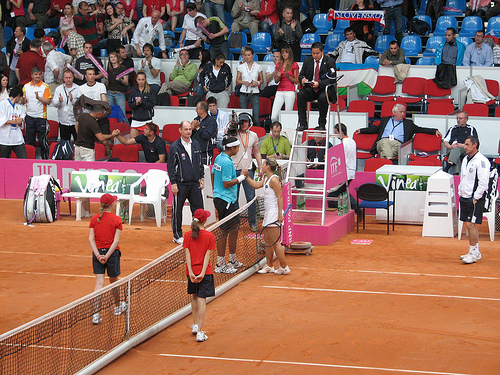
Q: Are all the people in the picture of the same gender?
A: No, they are both male and female.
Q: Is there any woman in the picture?
A: Yes, there are women.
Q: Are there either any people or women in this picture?
A: Yes, there are women.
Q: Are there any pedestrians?
A: No, there are no pedestrians.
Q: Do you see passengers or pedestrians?
A: No, there are no pedestrians or passengers.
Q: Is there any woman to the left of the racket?
A: Yes, there are women to the left of the racket.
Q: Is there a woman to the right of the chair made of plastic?
A: Yes, there are women to the right of the chair.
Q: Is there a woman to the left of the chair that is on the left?
A: No, the women are to the right of the chair.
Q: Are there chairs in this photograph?
A: Yes, there is a chair.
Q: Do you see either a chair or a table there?
A: Yes, there is a chair.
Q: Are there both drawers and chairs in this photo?
A: No, there is a chair but no drawers.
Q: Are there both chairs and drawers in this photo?
A: No, there is a chair but no drawers.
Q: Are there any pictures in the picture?
A: No, there are no pictures.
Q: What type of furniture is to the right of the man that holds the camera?
A: The piece of furniture is a chair.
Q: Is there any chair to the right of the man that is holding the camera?
A: Yes, there is a chair to the right of the man.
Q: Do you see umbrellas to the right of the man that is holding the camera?
A: No, there is a chair to the right of the man.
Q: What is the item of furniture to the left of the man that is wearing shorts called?
A: The piece of furniture is a chair.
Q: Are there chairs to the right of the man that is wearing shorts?
A: No, the chair is to the left of the man.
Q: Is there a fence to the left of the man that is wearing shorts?
A: No, there is a chair to the left of the man.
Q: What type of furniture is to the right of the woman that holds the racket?
A: The piece of furniture is a chair.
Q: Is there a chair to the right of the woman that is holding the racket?
A: Yes, there is a chair to the right of the woman.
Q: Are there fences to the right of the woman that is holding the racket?
A: No, there is a chair to the right of the woman.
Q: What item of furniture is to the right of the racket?
A: The piece of furniture is a chair.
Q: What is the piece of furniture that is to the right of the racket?
A: The piece of furniture is a chair.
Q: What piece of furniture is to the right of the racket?
A: The piece of furniture is a chair.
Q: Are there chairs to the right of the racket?
A: Yes, there is a chair to the right of the racket.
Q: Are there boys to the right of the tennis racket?
A: No, there is a chair to the right of the tennis racket.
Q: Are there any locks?
A: No, there are no locks.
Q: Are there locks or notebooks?
A: No, there are no locks or notebooks.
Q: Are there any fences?
A: No, there are no fences.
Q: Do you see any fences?
A: No, there are no fences.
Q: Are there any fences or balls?
A: No, there are no fences or balls.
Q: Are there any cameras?
A: Yes, there is a camera.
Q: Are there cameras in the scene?
A: Yes, there is a camera.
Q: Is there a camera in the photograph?
A: Yes, there is a camera.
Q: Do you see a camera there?
A: Yes, there is a camera.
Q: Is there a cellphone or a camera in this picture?
A: Yes, there is a camera.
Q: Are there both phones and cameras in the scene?
A: No, there is a camera but no phones.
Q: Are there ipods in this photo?
A: No, there are no ipods.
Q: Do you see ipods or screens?
A: No, there are no ipods or screens.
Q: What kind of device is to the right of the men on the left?
A: The device is a camera.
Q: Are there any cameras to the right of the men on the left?
A: Yes, there is a camera to the right of the men.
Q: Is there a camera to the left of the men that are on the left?
A: No, the camera is to the right of the men.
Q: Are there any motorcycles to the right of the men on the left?
A: No, there is a camera to the right of the men.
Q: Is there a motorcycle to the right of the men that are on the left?
A: No, there is a camera to the right of the men.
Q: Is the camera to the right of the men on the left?
A: Yes, the camera is to the right of the men.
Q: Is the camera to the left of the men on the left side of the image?
A: No, the camera is to the right of the men.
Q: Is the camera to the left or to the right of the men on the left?
A: The camera is to the right of the men.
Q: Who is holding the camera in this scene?
A: The man is holding the camera.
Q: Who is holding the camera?
A: The man is holding the camera.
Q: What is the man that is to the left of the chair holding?
A: The man is holding the camera.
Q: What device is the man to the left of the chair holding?
A: The man is holding the camera.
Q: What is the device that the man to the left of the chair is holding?
A: The device is a camera.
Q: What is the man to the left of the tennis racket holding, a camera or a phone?
A: The man is holding a camera.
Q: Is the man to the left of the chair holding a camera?
A: Yes, the man is holding a camera.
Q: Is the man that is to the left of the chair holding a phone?
A: No, the man is holding a camera.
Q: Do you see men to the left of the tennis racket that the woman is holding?
A: Yes, there is a man to the left of the racket.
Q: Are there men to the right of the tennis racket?
A: No, the man is to the left of the tennis racket.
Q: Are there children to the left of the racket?
A: No, there is a man to the left of the racket.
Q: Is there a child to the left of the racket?
A: No, there is a man to the left of the racket.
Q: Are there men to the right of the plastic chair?
A: Yes, there is a man to the right of the chair.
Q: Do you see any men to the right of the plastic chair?
A: Yes, there is a man to the right of the chair.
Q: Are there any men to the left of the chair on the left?
A: No, the man is to the right of the chair.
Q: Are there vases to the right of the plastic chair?
A: No, there is a man to the right of the chair.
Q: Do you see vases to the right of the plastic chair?
A: No, there is a man to the right of the chair.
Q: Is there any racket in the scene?
A: Yes, there is a racket.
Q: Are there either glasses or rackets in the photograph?
A: Yes, there is a racket.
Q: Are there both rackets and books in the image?
A: No, there is a racket but no books.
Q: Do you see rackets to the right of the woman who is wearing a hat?
A: Yes, there is a racket to the right of the woman.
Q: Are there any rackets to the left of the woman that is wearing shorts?
A: No, the racket is to the right of the woman.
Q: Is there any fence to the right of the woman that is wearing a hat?
A: No, there is a racket to the right of the woman.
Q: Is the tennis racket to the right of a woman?
A: Yes, the tennis racket is to the right of a woman.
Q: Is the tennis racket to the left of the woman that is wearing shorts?
A: No, the tennis racket is to the right of the woman.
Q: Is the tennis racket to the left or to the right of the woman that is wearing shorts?
A: The tennis racket is to the right of the woman.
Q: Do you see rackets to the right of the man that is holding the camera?
A: Yes, there is a racket to the right of the man.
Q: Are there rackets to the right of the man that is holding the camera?
A: Yes, there is a racket to the right of the man.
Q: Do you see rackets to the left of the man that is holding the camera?
A: No, the racket is to the right of the man.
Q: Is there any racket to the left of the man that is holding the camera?
A: No, the racket is to the right of the man.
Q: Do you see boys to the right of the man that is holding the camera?
A: No, there is a racket to the right of the man.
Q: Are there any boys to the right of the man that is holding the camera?
A: No, there is a racket to the right of the man.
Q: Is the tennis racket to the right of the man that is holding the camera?
A: Yes, the tennis racket is to the right of the man.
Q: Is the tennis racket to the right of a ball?
A: No, the tennis racket is to the right of the man.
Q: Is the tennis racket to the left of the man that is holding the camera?
A: No, the tennis racket is to the right of the man.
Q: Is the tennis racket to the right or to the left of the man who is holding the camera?
A: The tennis racket is to the right of the man.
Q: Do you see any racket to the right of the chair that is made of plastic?
A: Yes, there is a racket to the right of the chair.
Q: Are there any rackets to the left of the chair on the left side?
A: No, the racket is to the right of the chair.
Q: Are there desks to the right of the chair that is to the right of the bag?
A: No, there is a racket to the right of the chair.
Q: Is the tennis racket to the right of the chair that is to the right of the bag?
A: Yes, the tennis racket is to the right of the chair.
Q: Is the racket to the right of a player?
A: No, the racket is to the right of the chair.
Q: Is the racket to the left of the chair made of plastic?
A: No, the racket is to the right of the chair.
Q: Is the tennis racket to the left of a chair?
A: Yes, the tennis racket is to the left of a chair.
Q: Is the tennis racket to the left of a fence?
A: No, the tennis racket is to the left of a chair.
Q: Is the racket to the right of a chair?
A: No, the racket is to the left of a chair.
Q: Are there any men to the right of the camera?
A: Yes, there is a man to the right of the camera.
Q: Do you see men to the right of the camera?
A: Yes, there is a man to the right of the camera.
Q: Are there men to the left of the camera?
A: No, the man is to the right of the camera.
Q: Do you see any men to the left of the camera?
A: No, the man is to the right of the camera.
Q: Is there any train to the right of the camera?
A: No, there is a man to the right of the camera.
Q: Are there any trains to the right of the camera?
A: No, there is a man to the right of the camera.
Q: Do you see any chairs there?
A: Yes, there is a chair.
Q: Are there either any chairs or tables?
A: Yes, there is a chair.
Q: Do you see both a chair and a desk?
A: No, there is a chair but no desks.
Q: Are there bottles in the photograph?
A: No, there are no bottles.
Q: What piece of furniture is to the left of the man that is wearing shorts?
A: The piece of furniture is a chair.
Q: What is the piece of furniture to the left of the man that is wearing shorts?
A: The piece of furniture is a chair.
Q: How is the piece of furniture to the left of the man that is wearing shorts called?
A: The piece of furniture is a chair.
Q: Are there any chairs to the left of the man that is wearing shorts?
A: Yes, there is a chair to the left of the man.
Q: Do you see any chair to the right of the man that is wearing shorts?
A: No, the chair is to the left of the man.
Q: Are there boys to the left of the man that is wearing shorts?
A: No, there is a chair to the left of the man.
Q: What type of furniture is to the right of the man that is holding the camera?
A: The piece of furniture is a chair.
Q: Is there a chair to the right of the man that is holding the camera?
A: Yes, there is a chair to the right of the man.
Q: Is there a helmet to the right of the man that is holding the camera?
A: No, there is a chair to the right of the man.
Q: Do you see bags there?
A: Yes, there is a bag.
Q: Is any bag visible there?
A: Yes, there is a bag.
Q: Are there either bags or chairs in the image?
A: Yes, there is a bag.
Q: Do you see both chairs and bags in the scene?
A: Yes, there are both a bag and a chair.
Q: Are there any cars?
A: No, there are no cars.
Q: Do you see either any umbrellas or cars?
A: No, there are no cars or umbrellas.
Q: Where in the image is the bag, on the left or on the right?
A: The bag is on the left of the image.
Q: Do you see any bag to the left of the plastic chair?
A: Yes, there is a bag to the left of the chair.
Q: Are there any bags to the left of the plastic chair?
A: Yes, there is a bag to the left of the chair.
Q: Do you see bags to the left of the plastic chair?
A: Yes, there is a bag to the left of the chair.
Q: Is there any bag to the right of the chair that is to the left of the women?
A: No, the bag is to the left of the chair.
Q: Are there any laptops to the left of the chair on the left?
A: No, there is a bag to the left of the chair.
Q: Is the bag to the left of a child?
A: No, the bag is to the left of the chair.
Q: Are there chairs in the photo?
A: Yes, there is a chair.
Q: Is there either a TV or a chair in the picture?
A: Yes, there is a chair.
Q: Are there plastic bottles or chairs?
A: Yes, there is a plastic chair.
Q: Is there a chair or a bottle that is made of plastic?
A: Yes, the chair is made of plastic.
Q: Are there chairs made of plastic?
A: Yes, there is a chair that is made of plastic.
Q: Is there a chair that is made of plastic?
A: Yes, there is a chair that is made of plastic.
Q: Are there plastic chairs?
A: Yes, there is a chair that is made of plastic.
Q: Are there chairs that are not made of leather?
A: Yes, there is a chair that is made of plastic.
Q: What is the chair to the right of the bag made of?
A: The chair is made of plastic.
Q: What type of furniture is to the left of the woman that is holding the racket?
A: The piece of furniture is a chair.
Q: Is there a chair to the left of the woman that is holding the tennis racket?
A: Yes, there is a chair to the left of the woman.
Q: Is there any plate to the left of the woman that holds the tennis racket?
A: No, there is a chair to the left of the woman.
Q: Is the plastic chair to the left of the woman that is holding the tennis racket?
A: Yes, the chair is to the left of the woman.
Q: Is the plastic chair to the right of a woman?
A: No, the chair is to the left of a woman.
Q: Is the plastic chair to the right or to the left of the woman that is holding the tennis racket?
A: The chair is to the left of the woman.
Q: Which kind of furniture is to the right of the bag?
A: The piece of furniture is a chair.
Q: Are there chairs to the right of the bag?
A: Yes, there is a chair to the right of the bag.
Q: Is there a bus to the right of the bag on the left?
A: No, there is a chair to the right of the bag.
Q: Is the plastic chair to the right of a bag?
A: Yes, the chair is to the right of a bag.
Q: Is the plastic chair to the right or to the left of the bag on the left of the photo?
A: The chair is to the right of the bag.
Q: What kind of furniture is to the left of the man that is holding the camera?
A: The piece of furniture is a chair.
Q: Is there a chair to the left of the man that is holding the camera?
A: Yes, there is a chair to the left of the man.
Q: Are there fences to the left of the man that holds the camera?
A: No, there is a chair to the left of the man.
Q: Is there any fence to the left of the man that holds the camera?
A: No, there is a chair to the left of the man.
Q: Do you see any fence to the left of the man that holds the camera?
A: No, there is a chair to the left of the man.